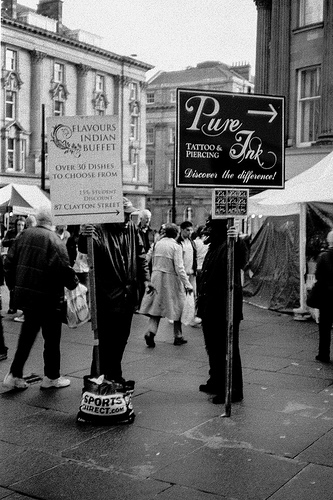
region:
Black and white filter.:
[2, 2, 328, 497]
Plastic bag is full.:
[74, 369, 136, 435]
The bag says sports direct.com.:
[72, 370, 137, 429]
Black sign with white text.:
[170, 81, 287, 196]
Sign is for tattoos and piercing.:
[173, 81, 288, 189]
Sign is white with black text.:
[39, 109, 127, 225]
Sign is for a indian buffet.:
[42, 112, 127, 225]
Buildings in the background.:
[1, 1, 331, 199]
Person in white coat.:
[141, 227, 186, 324]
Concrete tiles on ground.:
[3, 291, 328, 499]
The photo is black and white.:
[4, 5, 328, 496]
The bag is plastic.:
[76, 366, 135, 431]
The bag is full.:
[70, 364, 133, 428]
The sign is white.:
[44, 111, 129, 231]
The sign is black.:
[169, 81, 286, 191]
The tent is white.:
[229, 144, 331, 229]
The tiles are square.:
[19, 317, 328, 494]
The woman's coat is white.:
[140, 224, 190, 324]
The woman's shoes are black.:
[141, 313, 187, 352]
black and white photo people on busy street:
[40, 95, 312, 390]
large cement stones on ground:
[147, 421, 272, 480]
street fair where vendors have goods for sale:
[205, 139, 322, 333]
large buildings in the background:
[119, 32, 167, 178]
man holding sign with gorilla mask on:
[190, 199, 248, 260]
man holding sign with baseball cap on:
[69, 191, 137, 401]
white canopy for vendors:
[238, 156, 331, 333]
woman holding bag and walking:
[142, 218, 199, 351]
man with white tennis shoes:
[5, 342, 68, 398]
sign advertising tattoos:
[170, 85, 280, 182]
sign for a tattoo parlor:
[183, 101, 275, 169]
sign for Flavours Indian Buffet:
[72, 122, 116, 150]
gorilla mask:
[202, 216, 223, 240]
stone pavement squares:
[20, 429, 314, 496]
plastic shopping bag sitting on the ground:
[85, 380, 127, 424]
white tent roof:
[295, 178, 331, 198]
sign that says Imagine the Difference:
[184, 168, 276, 178]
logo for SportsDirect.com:
[83, 395, 122, 413]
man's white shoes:
[4, 374, 71, 387]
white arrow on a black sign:
[248, 103, 277, 121]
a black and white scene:
[47, 21, 277, 418]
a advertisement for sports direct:
[85, 383, 187, 445]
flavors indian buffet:
[36, 89, 152, 246]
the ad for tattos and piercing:
[174, 66, 291, 195]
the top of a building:
[6, 28, 193, 76]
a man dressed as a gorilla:
[194, 203, 283, 392]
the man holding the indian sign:
[26, 216, 161, 377]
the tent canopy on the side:
[262, 169, 312, 306]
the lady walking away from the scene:
[137, 213, 177, 356]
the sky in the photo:
[133, 7, 230, 48]